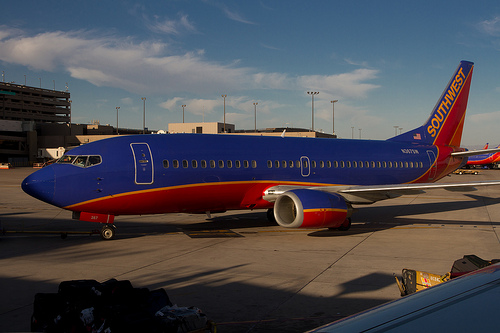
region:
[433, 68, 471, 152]
southwest written on the tail of the plane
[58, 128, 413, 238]
airplane is red and blue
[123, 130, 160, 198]
door on the airplane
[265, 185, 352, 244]
an engine on the airplane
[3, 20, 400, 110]
large white clouds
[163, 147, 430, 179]
passenger windows on the airplane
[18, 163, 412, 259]
airplane of the tarmac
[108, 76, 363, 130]
lights at the airport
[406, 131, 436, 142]
American flag painted on the airplane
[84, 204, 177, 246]
one of the wheels of the plane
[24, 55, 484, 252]
airplane parked on tarmac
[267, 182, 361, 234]
jet engine under wing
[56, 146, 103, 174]
cockpit window on front of plane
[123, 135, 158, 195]
door on front side of plane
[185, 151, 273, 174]
windows on side for passengers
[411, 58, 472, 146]
name of airline on tail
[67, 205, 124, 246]
open door on landing gear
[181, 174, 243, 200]
blue, yellow and red body of plane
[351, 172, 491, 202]
wing on side of plane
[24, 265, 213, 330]
luggage sitting in shade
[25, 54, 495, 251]
plane is blue and red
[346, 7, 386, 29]
part of the sky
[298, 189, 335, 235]
part of the left engine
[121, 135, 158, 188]
part of the door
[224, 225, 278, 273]
part of a runway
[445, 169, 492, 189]
part of a left wing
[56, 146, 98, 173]
part of a window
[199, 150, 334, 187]
section of some windows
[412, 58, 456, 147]
part of the tail wing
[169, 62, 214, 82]
part of the cloud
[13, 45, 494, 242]
a southwest airplane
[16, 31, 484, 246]
a white red orange and blue airplane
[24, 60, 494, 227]
a red blue and orange southwest airplane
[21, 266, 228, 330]
stacks of suitcases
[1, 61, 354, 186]
a airport building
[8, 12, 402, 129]
white clouds in the blue sky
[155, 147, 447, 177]
small windows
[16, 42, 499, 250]
small windows on a airplane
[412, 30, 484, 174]
orange southwest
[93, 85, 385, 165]
tall lights on a airport